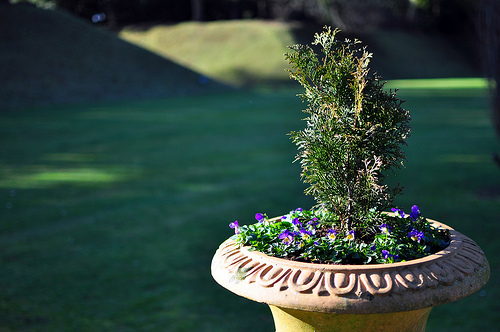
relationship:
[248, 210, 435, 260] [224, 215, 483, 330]
center of pot holder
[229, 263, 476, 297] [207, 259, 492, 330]
design on holder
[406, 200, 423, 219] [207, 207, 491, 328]
pansy in pot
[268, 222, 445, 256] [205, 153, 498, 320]
pansy in pot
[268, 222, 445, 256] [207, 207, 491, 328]
pansy in pot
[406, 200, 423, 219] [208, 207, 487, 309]
pansy in pot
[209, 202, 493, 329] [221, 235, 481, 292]
plant pot with pattern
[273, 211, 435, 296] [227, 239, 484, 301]
soil in planter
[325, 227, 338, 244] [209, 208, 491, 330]
flower at base of planter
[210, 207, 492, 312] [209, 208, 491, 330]
base at base of planter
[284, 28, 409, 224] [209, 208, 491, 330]
bush in planter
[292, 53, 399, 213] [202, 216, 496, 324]
plant with pot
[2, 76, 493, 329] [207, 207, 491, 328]
lawn with pot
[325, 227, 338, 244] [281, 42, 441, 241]
flower with plant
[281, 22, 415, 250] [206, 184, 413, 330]
plant in pot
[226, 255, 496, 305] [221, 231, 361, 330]
design on pot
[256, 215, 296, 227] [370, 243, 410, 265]
leaves on plant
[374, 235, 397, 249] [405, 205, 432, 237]
leaves on plant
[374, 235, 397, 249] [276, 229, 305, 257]
leaves on plant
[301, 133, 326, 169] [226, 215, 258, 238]
leaves on plant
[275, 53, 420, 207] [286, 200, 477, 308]
tree in pot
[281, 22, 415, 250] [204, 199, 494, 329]
plant in pot holder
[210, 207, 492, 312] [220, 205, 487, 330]
base on pot holder